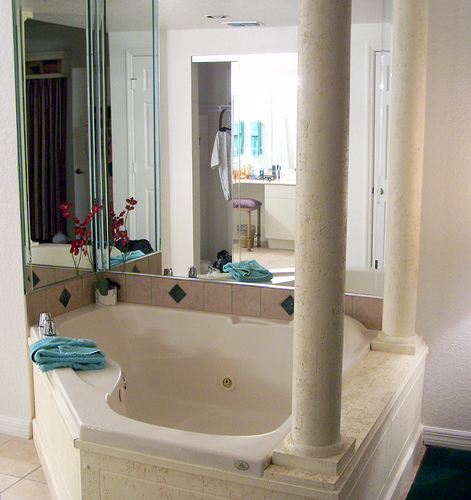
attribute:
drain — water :
[207, 365, 237, 393]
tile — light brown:
[4, 442, 38, 499]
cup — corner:
[94, 284, 118, 303]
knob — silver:
[41, 319, 55, 336]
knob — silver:
[40, 311, 50, 327]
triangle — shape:
[161, 277, 198, 308]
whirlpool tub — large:
[37, 295, 370, 477]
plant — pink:
[55, 201, 106, 280]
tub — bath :
[29, 303, 425, 496]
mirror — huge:
[93, 6, 407, 291]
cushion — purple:
[231, 193, 263, 209]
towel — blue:
[32, 334, 101, 370]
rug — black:
[394, 415, 469, 498]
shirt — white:
[209, 128, 243, 197]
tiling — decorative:
[22, 269, 383, 331]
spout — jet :
[219, 373, 237, 391]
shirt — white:
[211, 125, 245, 204]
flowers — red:
[60, 201, 110, 258]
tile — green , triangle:
[404, 448, 456, 494]